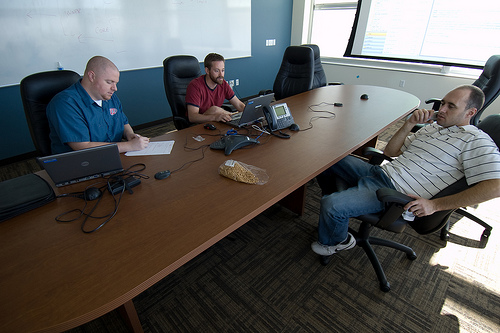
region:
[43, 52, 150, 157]
person sitting at a large table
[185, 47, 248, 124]
person sitting at a large table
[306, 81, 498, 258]
person sitting at a large table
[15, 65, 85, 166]
black leather executive chair at a table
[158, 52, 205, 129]
black leather executive chair at a table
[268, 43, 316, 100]
black leather executive chair at a table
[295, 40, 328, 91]
black leather executive chair at a table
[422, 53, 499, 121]
black leather executive chair at a table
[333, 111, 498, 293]
black leather executive chair at a table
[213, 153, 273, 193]
bag of food on the table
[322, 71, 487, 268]
A person seated on a chair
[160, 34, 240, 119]
A person seated on a chair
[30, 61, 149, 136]
A person seated on a chair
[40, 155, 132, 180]
A grey computer laptop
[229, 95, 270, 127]
A grey computer laptop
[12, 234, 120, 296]
A smooth brown table surface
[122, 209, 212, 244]
A smooth brown table surface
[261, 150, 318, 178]
A smooth brown table surface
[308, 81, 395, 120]
A smooth brown table surface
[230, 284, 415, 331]
A black and brown floor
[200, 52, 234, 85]
head of a person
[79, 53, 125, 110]
head of a person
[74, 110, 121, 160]
arm of a person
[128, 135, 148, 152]
hand of a person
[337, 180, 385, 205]
thigh of a person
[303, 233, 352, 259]
feet of a person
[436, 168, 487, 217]
arm of a person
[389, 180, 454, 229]
hand of a person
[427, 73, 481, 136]
head of a person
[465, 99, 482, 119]
ear of a person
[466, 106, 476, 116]
ear of a person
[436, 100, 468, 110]
eye of a person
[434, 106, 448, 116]
nose of a person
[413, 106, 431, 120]
fingers of a person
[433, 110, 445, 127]
mouth of a person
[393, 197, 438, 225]
hand of a person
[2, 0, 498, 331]
underpopulated work conference in largely empty conference room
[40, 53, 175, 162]
worker dude, writing with a pen or pencil on a piece of white paper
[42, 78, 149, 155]
worker dude in dark blue uniform shirt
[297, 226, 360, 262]
one white sneaker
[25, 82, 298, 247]
two laptops, minimum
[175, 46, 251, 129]
huppster [yuppie=hipster] wearing requisite identical beard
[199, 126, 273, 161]
hub of some sort that looks like video game controller thing but isnt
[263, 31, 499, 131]
three empty office chairs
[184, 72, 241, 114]
red ringer t-shirt w/ dark ringers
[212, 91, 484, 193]
slightly older guy completely focussed on bag of nuts